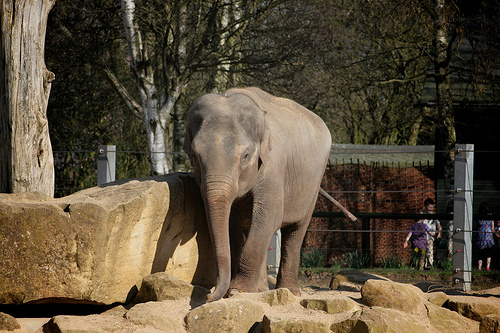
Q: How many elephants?
A: One.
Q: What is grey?
A: Elephant.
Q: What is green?
A: Tree.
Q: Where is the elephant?
A: Zoo.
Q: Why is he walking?
A: Going to get food.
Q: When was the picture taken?
A: Daytime.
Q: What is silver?
A: Fence.